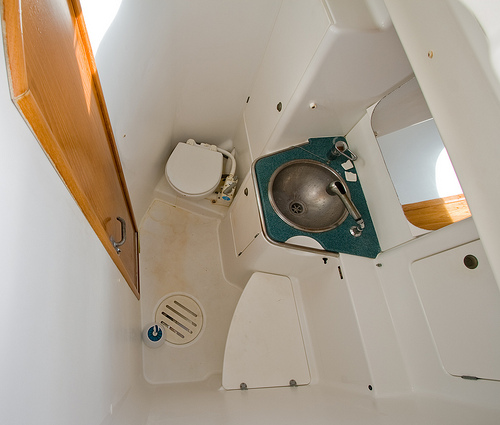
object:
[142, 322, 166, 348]
plug floor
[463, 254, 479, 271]
hole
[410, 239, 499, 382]
sink cover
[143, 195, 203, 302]
stain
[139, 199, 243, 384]
bathroom floor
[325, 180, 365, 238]
faucet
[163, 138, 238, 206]
toilet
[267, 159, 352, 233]
bowl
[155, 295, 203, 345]
drain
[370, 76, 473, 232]
mirror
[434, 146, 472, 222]
reflection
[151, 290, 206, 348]
white grate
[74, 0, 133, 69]
light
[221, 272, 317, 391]
seat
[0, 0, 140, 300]
door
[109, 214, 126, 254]
door knob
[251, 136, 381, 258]
counter top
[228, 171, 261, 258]
access door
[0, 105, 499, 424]
wall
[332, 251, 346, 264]
corner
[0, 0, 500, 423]
bathroom